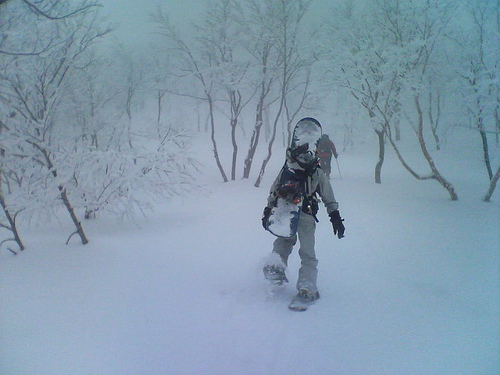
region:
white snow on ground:
[111, 257, 146, 287]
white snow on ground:
[149, 246, 203, 293]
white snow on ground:
[75, 316, 125, 364]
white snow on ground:
[144, 310, 179, 352]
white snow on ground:
[301, 321, 345, 356]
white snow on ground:
[348, 273, 393, 313]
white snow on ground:
[384, 213, 427, 259]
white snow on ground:
[409, 279, 448, 319]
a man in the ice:
[256, 110, 364, 309]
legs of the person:
[273, 219, 335, 273]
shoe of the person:
[258, 242, 350, 334]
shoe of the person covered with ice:
[253, 228, 300, 300]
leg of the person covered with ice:
[258, 256, 317, 321]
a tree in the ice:
[35, 162, 113, 249]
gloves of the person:
[332, 206, 362, 250]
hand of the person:
[313, 197, 360, 252]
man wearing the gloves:
[322, 192, 362, 241]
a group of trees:
[47, 28, 497, 175]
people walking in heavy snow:
[221, 85, 379, 340]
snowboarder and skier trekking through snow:
[242, 105, 397, 333]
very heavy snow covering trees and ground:
[5, 32, 211, 317]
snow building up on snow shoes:
[258, 245, 353, 324]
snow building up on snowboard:
[257, 101, 360, 282]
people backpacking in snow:
[248, 103, 367, 324]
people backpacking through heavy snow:
[250, 87, 367, 337]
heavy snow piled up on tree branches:
[5, 30, 179, 275]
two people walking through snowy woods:
[222, 87, 388, 341]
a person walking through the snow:
[250, 95, 363, 334]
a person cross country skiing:
[320, 124, 357, 200]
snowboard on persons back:
[283, 127, 313, 271]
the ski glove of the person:
[316, 198, 354, 246]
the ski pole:
[333, 148, 349, 190]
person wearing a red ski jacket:
[319, 128, 341, 178]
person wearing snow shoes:
[250, 249, 335, 329]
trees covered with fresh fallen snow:
[1, 34, 194, 244]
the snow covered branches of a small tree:
[62, 123, 203, 221]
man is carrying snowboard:
[268, 124, 308, 213]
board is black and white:
[263, 127, 330, 232]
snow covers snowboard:
[263, 119, 312, 233]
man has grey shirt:
[296, 148, 334, 206]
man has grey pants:
[285, 206, 317, 295]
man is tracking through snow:
[232, 246, 330, 345]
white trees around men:
[25, 15, 498, 235]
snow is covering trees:
[7, 17, 465, 206]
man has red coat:
[318, 138, 330, 162]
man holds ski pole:
[331, 145, 345, 187]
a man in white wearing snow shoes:
[254, 113, 354, 315]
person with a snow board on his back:
[259, 111, 349, 317]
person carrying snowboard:
[254, 112, 349, 317]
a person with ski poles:
[315, 127, 344, 184]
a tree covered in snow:
[305, 20, 470, 202]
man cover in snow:
[249, 109, 356, 316]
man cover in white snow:
[254, 117, 344, 317]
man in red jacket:
[318, 128, 348, 191]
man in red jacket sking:
[315, 131, 345, 189]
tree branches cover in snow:
[55, 119, 205, 243]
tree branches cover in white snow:
[33, 121, 209, 248]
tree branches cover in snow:
[345, 42, 467, 201]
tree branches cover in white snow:
[174, 61, 344, 195]